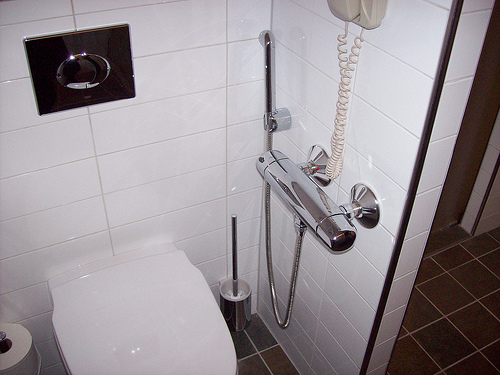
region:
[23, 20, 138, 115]
chrome plate on wall above toilet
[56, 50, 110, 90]
round button in center of plate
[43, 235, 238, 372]
white toilet is closed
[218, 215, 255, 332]
scrub brush to the right of toilet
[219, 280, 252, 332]
scrub brush in cup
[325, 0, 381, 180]
phone attached to the wall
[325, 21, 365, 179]
phone cord is hanging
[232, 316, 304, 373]
floor is brown tile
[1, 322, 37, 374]
white toilet paper to the left of toilet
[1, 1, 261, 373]
white tile wall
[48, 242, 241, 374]
a white toilet in a bathroom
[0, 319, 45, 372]
a roll of toilet paper next to a toilet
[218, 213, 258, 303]
a toilet scrub brush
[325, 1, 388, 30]
a phone in a bathroom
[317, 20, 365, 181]
a spiral phone cord attached to a phone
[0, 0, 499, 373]
a tiled bathroom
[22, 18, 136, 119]
a toilet flusher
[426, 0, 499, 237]
a bathroom door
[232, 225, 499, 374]
brown tile on a bathroom floor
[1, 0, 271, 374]
a white tiled wall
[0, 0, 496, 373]
bathroom facility with white wall tile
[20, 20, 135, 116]
toilet-flushing sensor on wall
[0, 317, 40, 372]
white roll of toilet paper on spindle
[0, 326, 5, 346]
top of toilet paper spindle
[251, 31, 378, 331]
silver-tone wall-mounted dryer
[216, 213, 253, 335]
silver-tone toilet cleaning brush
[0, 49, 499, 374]
white tiles on wall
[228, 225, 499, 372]
dark tiles on floor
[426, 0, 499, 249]
entry door to bathroom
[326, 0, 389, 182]
cream-colored phone mounted on wall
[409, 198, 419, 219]
part of a wall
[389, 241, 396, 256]
edge of a wall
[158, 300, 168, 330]
part of a tank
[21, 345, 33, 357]
part of a tissue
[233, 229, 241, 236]
part of a stem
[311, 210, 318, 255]
part of a rail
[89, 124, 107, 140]
edge of a tissue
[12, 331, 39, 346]
part of a tissue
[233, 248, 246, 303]
part of a scrub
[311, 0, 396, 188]
telephone attached to wall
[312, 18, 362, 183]
cord hanging from telephone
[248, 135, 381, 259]
handlebar attached to wall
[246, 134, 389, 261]
handlebar on wall is silver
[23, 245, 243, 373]
toilet bowl attached to wall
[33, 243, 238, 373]
toilet bowl in bathroom is white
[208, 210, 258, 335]
toilet bowl brush in canister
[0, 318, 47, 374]
roll of toilet paper beside toilet bowl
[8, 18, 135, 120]
silver attachment against wall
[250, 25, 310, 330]
pipe running down wall